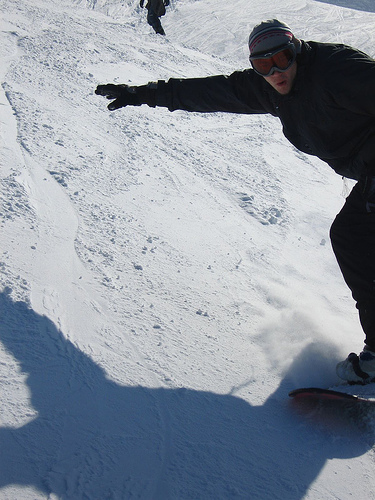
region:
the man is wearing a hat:
[242, 19, 295, 54]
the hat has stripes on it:
[245, 19, 297, 51]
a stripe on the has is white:
[250, 19, 292, 46]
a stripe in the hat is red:
[249, 25, 295, 47]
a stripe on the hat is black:
[243, 22, 301, 49]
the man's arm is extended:
[100, 69, 278, 131]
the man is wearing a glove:
[92, 78, 145, 109]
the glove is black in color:
[96, 82, 155, 108]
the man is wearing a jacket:
[154, 41, 374, 173]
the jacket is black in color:
[154, 46, 373, 172]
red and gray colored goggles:
[248, 40, 297, 78]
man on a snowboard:
[93, 19, 373, 408]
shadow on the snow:
[0, 291, 373, 498]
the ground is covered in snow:
[5, 3, 374, 498]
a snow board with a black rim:
[287, 383, 373, 406]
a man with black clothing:
[95, 17, 374, 383]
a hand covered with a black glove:
[94, 82, 157, 112]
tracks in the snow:
[2, 0, 372, 497]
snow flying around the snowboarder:
[255, 269, 360, 427]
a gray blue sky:
[317, 0, 373, 12]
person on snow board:
[133, 23, 371, 431]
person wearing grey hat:
[232, 15, 300, 62]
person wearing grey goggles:
[240, 38, 310, 77]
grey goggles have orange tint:
[248, 45, 306, 79]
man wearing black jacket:
[135, 34, 374, 190]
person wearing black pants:
[303, 159, 372, 358]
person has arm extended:
[119, 59, 293, 139]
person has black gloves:
[88, 65, 139, 118]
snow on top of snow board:
[297, 348, 374, 427]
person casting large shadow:
[3, 265, 364, 498]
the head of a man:
[243, 16, 338, 109]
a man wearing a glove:
[78, 67, 174, 143]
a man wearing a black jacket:
[109, 29, 373, 209]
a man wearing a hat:
[243, 9, 327, 104]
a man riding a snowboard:
[123, 28, 372, 439]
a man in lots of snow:
[176, 6, 371, 437]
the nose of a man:
[270, 63, 288, 90]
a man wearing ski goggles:
[243, 0, 358, 91]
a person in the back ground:
[128, 0, 191, 55]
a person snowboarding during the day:
[141, 1, 171, 42]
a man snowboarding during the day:
[80, 14, 370, 415]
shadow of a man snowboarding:
[16, 348, 372, 493]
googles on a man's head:
[246, 39, 310, 81]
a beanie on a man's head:
[245, 19, 296, 62]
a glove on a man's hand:
[86, 79, 193, 118]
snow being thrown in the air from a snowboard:
[233, 249, 346, 350]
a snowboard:
[262, 328, 371, 407]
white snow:
[106, 199, 248, 319]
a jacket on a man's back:
[114, 36, 373, 195]